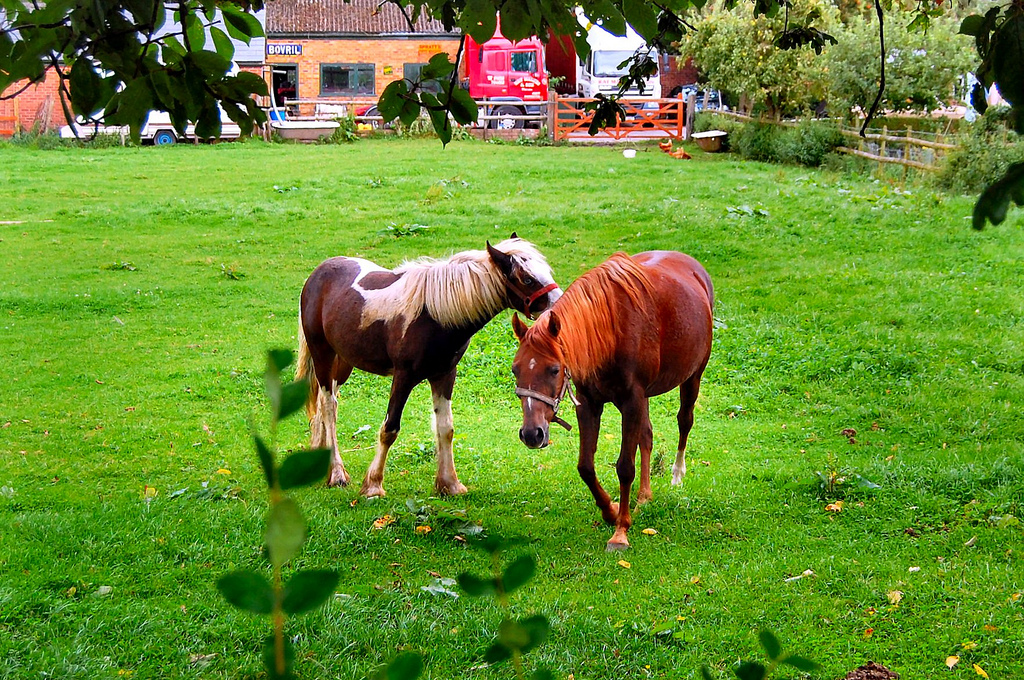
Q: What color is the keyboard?
A: Black.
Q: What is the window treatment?
A: White blinds.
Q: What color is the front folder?
A: Yellow.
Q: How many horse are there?
A: Two.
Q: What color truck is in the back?
A: Red.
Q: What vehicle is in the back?
A: The truck.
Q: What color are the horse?
A: Brown.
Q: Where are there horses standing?
A: Next to each other.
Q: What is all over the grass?
A: Leaves.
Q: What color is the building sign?
A: Blue.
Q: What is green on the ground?
A: The grass.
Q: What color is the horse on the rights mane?
A: Red.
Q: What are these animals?
A: They are horses.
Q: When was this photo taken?
A: It was taken early afternoon.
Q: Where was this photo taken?
A: In a field.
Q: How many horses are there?
A: There are 2.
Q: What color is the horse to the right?
A: It is an auburn color.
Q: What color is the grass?
A: It is green.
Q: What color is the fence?
A: It is brown.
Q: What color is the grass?
A: Green.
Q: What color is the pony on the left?
A: Brown and white.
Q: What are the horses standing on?
A: Grass.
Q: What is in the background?
A: A house.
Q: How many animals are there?
A: Two.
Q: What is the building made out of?
A: Brick.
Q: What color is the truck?
A: Red.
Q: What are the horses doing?
A: Standing.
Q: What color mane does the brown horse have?
A: Brown.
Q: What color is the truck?
A: Red.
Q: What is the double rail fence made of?
A: Wood.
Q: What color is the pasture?
A: Green.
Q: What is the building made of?
A: Bricks.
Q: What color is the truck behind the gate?
A: White.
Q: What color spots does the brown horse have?
A: White.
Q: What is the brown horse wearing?
A: Bridle.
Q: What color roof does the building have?
A: Brown.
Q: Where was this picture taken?
A: In the horse pasture.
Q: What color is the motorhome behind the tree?
A: White with blue rims.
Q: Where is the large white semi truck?
A: Beside the red one.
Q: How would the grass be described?
A: Bright green.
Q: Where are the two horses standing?
A: Beside each other.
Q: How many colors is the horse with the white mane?
A: Two.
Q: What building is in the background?
A: Farmhouse.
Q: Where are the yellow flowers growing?
A: In the grass.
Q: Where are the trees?
A: Next to the fence.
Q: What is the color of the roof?
A: Red.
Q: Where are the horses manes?
A: On their necks.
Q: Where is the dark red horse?
A: Next to the brown and white horse.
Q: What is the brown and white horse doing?
A: Sniffing the other horse.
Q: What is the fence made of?
A: Wood.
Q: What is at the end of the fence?
A: A large red gate.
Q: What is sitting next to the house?
A: A car with blue wheels.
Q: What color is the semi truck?
A: Red.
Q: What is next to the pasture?
A: Group of trees.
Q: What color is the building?
A: Orange.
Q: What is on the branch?
A: Leaves.